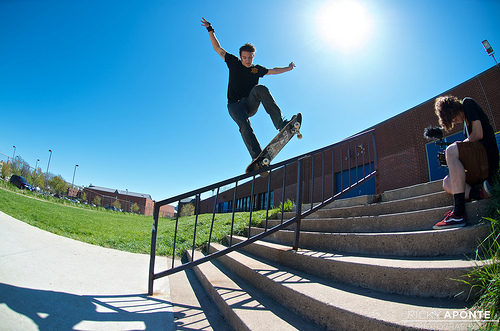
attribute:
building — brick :
[178, 61, 499, 208]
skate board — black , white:
[245, 112, 302, 175]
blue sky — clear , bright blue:
[1, 5, 498, 193]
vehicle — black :
[8, 171, 32, 191]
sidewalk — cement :
[0, 210, 178, 329]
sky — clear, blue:
[2, 3, 195, 152]